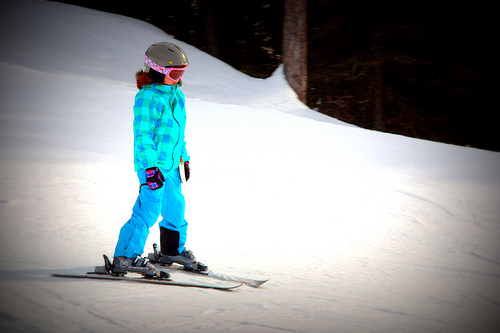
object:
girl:
[110, 40, 196, 277]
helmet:
[142, 41, 189, 87]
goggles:
[142, 52, 187, 81]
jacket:
[132, 83, 191, 173]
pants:
[113, 167, 188, 258]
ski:
[49, 271, 243, 290]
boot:
[111, 254, 157, 276]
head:
[143, 40, 190, 84]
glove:
[144, 167, 166, 190]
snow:
[0, 0, 500, 333]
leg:
[157, 167, 188, 257]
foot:
[157, 248, 198, 266]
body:
[111, 84, 197, 279]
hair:
[134, 68, 155, 91]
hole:
[167, 47, 176, 53]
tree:
[281, 0, 309, 105]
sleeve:
[131, 93, 164, 170]